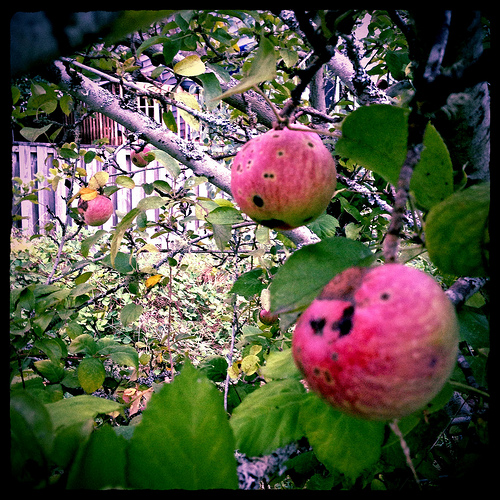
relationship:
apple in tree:
[290, 261, 459, 420] [25, 12, 487, 493]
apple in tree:
[228, 129, 337, 233] [25, 12, 487, 493]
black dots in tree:
[77, 194, 113, 227] [25, 12, 487, 493]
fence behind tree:
[66, 145, 153, 225] [76, 42, 210, 193]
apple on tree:
[290, 261, 459, 420] [25, 12, 487, 493]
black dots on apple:
[295, 289, 446, 408] [290, 261, 459, 420]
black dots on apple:
[229, 127, 319, 233] [228, 129, 337, 233]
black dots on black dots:
[126, 157, 149, 169] [129, 147, 150, 168]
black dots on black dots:
[78, 199, 93, 222] [77, 194, 113, 227]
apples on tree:
[55, 121, 465, 418] [29, 71, 466, 461]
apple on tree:
[295, 255, 473, 417] [29, 71, 466, 461]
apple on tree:
[228, 113, 332, 233] [29, 71, 466, 461]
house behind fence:
[55, 10, 303, 164] [8, 134, 237, 233]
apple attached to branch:
[228, 129, 337, 233] [261, 5, 380, 127]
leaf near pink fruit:
[126, 352, 238, 490] [290, 265, 455, 420]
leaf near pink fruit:
[126, 352, 238, 490] [231, 123, 334, 230]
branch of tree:
[56, 76, 256, 176] [25, 12, 487, 493]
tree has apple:
[25, 12, 487, 493] [290, 261, 459, 420]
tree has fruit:
[25, 12, 487, 493] [250, 297, 279, 326]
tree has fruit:
[25, 12, 487, 493] [65, 180, 120, 230]